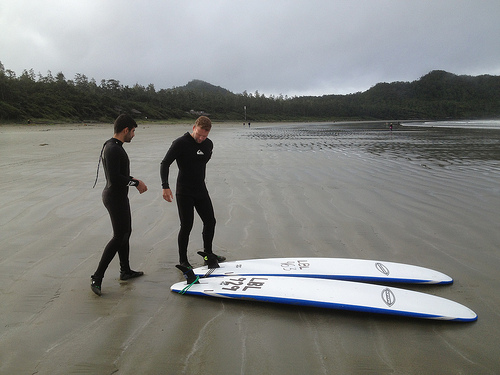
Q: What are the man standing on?
A: Wet sand.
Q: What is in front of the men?
A: Surfboards.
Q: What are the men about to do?
A: To surf.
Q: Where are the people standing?
A: On the beach.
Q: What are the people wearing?
A: Wetsuits.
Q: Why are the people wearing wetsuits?
A: To stay warm.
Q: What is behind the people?
A: Hills.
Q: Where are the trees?
A: On the hills.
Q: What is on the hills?
A: Trees.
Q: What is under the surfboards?
A: Sand.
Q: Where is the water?
A: Beside the sand.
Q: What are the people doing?
A: Standing.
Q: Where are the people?
A: At the beach.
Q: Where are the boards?
A: On the ground.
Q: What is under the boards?
A: Sand.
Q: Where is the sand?
A: At the beach.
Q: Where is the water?
A: On the right.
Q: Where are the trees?
A: On the hills.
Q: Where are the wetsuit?
A: On the people.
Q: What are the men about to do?
A: Surf.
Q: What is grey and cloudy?
A: A sky.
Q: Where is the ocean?
A: To the right.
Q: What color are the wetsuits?
A: Black.